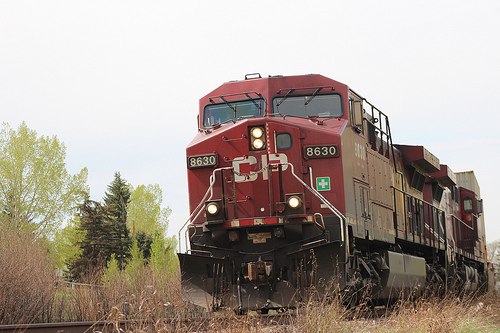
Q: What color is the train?
A: Red.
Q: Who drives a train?
A: Engineer.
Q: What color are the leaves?
A: Green.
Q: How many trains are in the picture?
A: One.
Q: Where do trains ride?
A: Tracks.